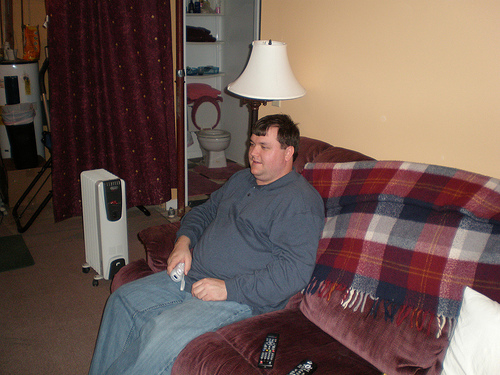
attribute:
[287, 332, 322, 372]
control — remote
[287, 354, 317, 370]
plastic — black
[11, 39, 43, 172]
heater — black, white, water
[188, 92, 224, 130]
cover — red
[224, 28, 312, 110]
shade — lamp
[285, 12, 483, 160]
wall — brown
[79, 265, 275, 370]
jeans — blue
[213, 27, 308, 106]
lampshade — white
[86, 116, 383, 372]
man — sitting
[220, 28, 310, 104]
shade — lamp, white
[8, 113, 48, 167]
can — trash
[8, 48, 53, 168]
heater — water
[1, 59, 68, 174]
heater — water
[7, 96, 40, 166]
can — trash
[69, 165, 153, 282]
object — white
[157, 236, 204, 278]
hand — man's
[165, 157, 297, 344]
shirt — long sleeved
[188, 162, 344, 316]
shirt — gray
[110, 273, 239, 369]
jeans — blue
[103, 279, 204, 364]
jeans — baggy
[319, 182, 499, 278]
blanket — wool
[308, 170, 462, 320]
blanket — flannel